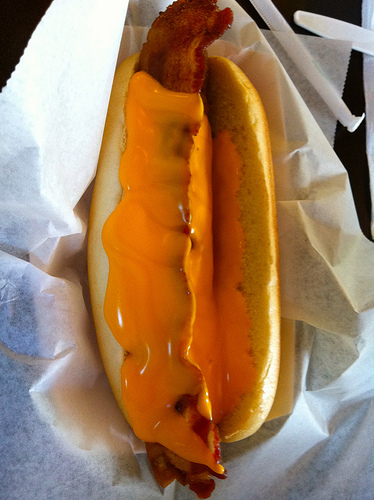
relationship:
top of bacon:
[105, 27, 262, 109] [121, 23, 253, 357]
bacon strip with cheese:
[121, 23, 253, 357] [134, 113, 244, 345]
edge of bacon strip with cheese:
[105, 27, 262, 109] [134, 113, 244, 345]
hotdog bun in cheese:
[71, 79, 289, 402] [134, 113, 244, 345]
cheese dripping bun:
[134, 113, 244, 345] [223, 81, 298, 273]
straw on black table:
[256, 8, 345, 81] [0, 0, 374, 499]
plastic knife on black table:
[256, 8, 345, 81] [0, 0, 374, 499]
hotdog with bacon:
[71, 79, 289, 402] [121, 23, 253, 357]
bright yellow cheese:
[123, 113, 208, 359] [134, 113, 244, 345]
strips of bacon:
[120, 45, 241, 213] [121, 23, 253, 357]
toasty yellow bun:
[129, 77, 289, 249] [223, 81, 298, 273]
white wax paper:
[277, 116, 352, 231] [267, 76, 322, 155]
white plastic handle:
[277, 116, 352, 231] [297, 9, 372, 66]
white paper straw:
[277, 116, 352, 231] [256, 8, 345, 81]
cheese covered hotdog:
[134, 113, 244, 345] [71, 79, 289, 402]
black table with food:
[264, 32, 335, 109] [120, 45, 241, 213]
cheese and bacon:
[134, 113, 244, 345] [121, 23, 253, 357]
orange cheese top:
[120, 45, 241, 213] [105, 27, 262, 109]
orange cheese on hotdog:
[134, 116, 187, 255] [71, 79, 289, 402]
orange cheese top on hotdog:
[134, 116, 187, 255] [71, 79, 289, 402]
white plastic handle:
[277, 116, 352, 231] [291, 9, 374, 56]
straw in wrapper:
[256, 8, 345, 81] [264, 32, 335, 109]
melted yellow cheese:
[140, 158, 245, 262] [134, 113, 244, 345]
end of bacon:
[138, 36, 219, 89] [121, 23, 253, 357]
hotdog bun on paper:
[71, 79, 289, 402] [267, 76, 322, 155]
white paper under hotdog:
[277, 116, 352, 231] [71, 79, 289, 402]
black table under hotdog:
[282, 60, 336, 116] [71, 79, 289, 402]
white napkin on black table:
[277, 116, 352, 231] [282, 60, 336, 116]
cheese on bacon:
[134, 113, 244, 345] [121, 23, 253, 357]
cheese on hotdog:
[134, 113, 244, 345] [71, 79, 289, 402]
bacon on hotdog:
[121, 23, 253, 357] [71, 79, 289, 402]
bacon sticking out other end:
[121, 23, 253, 357] [133, 17, 251, 85]